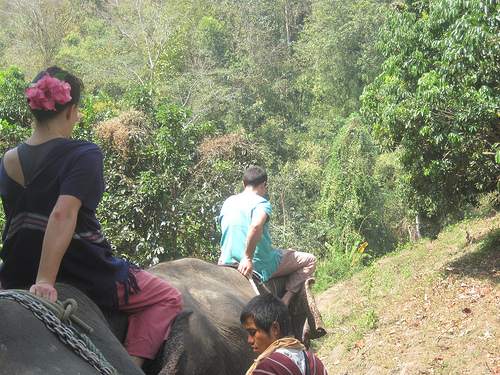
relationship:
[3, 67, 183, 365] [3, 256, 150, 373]
people riding elephant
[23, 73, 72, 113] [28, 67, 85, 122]
flower on hair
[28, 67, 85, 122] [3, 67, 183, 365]
hair of people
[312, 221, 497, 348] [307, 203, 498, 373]
grass on hill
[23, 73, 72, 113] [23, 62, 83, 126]
flower in hair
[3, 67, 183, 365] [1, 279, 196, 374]
people riding elephant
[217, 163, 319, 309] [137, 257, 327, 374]
man riding elephant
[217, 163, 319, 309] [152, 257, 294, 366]
man riding elephant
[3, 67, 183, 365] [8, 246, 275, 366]
people riding elephant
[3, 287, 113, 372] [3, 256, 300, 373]
chains draped over elephant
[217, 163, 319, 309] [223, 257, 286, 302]
man holding seat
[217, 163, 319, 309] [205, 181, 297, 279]
man wearing shirt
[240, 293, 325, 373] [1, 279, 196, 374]
man looking at elephant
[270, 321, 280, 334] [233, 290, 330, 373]
ear of boy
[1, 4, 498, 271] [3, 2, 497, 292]
trees on hill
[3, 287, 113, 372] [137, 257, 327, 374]
chains on elephant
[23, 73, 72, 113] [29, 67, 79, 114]
flower in hair